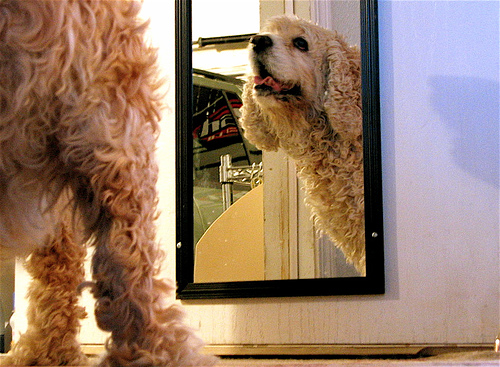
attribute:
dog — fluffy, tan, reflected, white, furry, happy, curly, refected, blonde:
[4, 9, 148, 316]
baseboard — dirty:
[278, 338, 480, 364]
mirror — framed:
[150, 6, 406, 304]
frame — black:
[355, 7, 387, 106]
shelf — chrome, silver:
[214, 135, 261, 216]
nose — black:
[254, 38, 276, 55]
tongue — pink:
[253, 71, 301, 95]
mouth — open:
[249, 53, 302, 100]